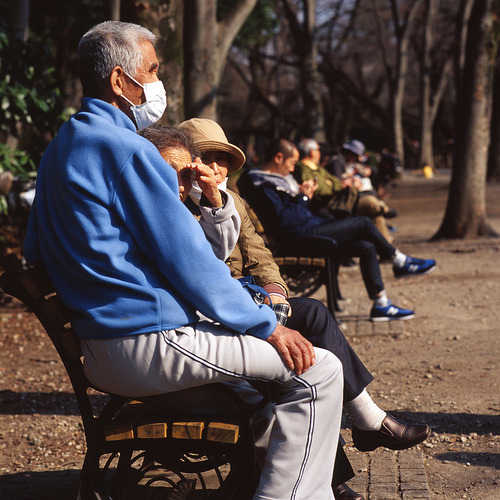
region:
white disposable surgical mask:
[113, 59, 170, 133]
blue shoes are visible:
[361, 230, 493, 348]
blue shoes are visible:
[344, 211, 442, 311]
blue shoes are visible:
[348, 225, 430, 382]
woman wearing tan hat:
[190, 117, 230, 152]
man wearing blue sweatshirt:
[94, 214, 163, 291]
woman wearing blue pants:
[308, 304, 330, 331]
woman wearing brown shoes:
[373, 416, 435, 452]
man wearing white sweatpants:
[323, 364, 336, 431]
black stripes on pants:
[307, 409, 318, 449]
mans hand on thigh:
[261, 309, 323, 383]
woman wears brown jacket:
[247, 236, 269, 268]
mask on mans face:
[136, 77, 166, 124]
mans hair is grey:
[86, 31, 128, 61]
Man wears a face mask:
[62, 10, 351, 482]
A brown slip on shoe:
[351, 404, 436, 468]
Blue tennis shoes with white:
[359, 253, 447, 330]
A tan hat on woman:
[178, 112, 253, 167]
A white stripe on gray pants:
[119, 313, 344, 498]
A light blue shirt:
[31, 98, 295, 386]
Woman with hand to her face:
[156, 138, 244, 241]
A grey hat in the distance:
[339, 133, 371, 160]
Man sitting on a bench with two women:
[31, 18, 377, 498]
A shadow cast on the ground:
[378, 380, 499, 478]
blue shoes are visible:
[365, 165, 465, 330]